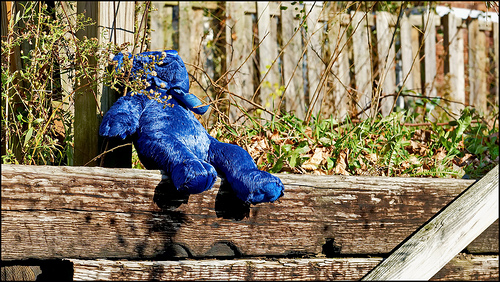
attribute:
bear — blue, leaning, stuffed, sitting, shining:
[91, 35, 285, 210]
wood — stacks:
[35, 171, 443, 281]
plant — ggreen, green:
[7, 18, 124, 156]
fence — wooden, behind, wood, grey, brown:
[228, 10, 470, 113]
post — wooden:
[62, 3, 146, 179]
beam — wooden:
[347, 15, 382, 201]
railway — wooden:
[321, 19, 480, 123]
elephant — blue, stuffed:
[111, 70, 221, 173]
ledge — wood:
[202, 166, 423, 269]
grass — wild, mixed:
[294, 77, 446, 181]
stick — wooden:
[71, 9, 150, 66]